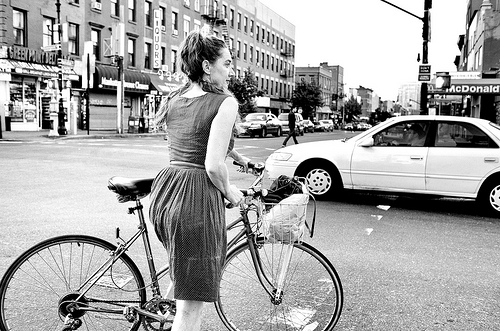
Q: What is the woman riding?
A: A bicycle.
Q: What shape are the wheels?
A: Circles.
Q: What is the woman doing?
A: Walking her bike across the street.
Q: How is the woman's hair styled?
A: In a ponytail.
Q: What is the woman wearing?
A: A dress.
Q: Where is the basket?
A: Attached to the bike.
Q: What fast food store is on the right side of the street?
A: McDonald's/.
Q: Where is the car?
A: At the intersection.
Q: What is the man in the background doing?
A: Crossing the street.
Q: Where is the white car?
A: At the intersection.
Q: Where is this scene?
A: In a city.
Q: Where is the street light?
A: At the intersection.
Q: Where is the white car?
A: Intersection.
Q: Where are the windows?
A: Above the businesses.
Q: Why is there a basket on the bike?
A: To carry items.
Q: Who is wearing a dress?
A: Girl on bicycle.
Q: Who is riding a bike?
A: Woman.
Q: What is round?
A: Tires.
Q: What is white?
A: Car.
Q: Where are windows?
A: On buildings.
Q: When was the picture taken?
A: Daytime.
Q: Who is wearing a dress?
A: The woman.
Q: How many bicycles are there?
A: One.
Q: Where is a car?
A: On the street.